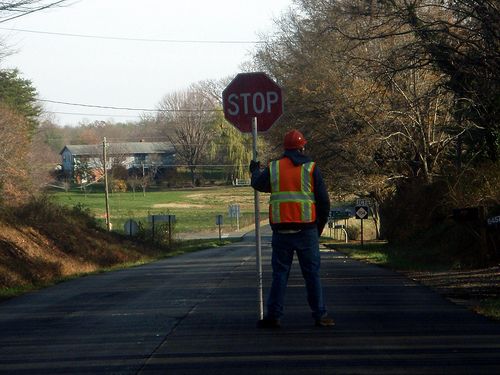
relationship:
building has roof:
[52, 138, 183, 187] [95, 133, 189, 158]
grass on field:
[64, 190, 187, 222] [64, 180, 256, 228]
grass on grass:
[343, 238, 388, 262] [64, 190, 187, 222]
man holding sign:
[248, 129, 332, 317] [222, 71, 281, 132]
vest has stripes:
[268, 156, 316, 223] [268, 156, 315, 222]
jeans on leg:
[265, 229, 325, 318] [257, 233, 294, 328]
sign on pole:
[218, 65, 288, 137] [224, 116, 302, 340]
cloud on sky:
[0, 4, 328, 126] [0, 0, 345, 123]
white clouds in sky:
[75, 30, 195, 104] [9, 2, 270, 115]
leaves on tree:
[331, 52, 378, 87] [321, 28, 413, 135]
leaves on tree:
[5, 80, 30, 114] [322, 4, 496, 222]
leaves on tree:
[256, 4, 482, 232] [262, 5, 498, 244]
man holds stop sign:
[248, 129, 332, 317] [221, 71, 286, 132]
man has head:
[248, 129, 336, 327] [276, 123, 312, 171]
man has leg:
[248, 129, 336, 327] [297, 227, 335, 329]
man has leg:
[248, 129, 336, 327] [260, 233, 294, 328]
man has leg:
[248, 129, 336, 327] [266, 234, 296, 334]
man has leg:
[248, 129, 336, 327] [298, 236, 333, 338]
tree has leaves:
[346, 2, 498, 271] [324, 54, 370, 122]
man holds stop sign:
[248, 129, 336, 327] [217, 65, 292, 322]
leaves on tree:
[319, 60, 355, 93] [237, 0, 499, 245]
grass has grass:
[50, 187, 250, 226] [104, 166, 235, 261]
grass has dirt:
[50, 187, 250, 226] [148, 187, 270, 213]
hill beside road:
[0, 201, 165, 298] [0, 221, 498, 374]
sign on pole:
[221, 71, 285, 133] [250, 116, 264, 321]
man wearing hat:
[248, 129, 336, 327] [260, 111, 332, 149]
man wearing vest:
[248, 129, 336, 327] [264, 154, 323, 221]